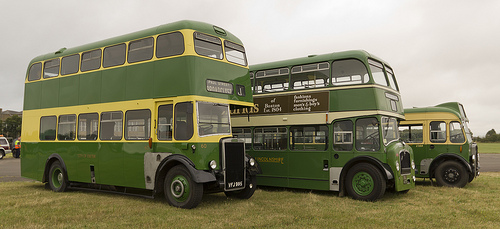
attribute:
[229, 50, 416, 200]
bus — parked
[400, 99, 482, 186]
bus — parked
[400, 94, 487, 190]
bus — green, yellow, single level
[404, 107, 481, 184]
bus — green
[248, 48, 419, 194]
bus — green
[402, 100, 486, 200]
bus — parked, single level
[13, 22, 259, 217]
bus — parked, green, yellow, double decker